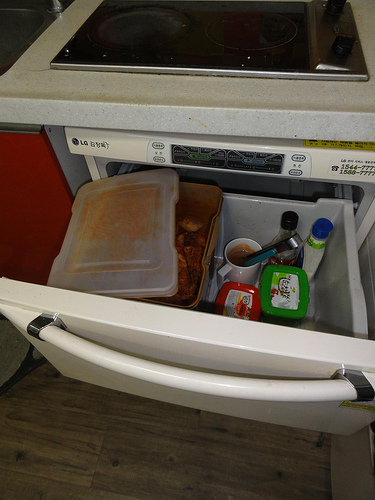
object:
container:
[258, 265, 309, 319]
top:
[215, 282, 260, 319]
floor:
[4, 355, 374, 500]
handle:
[25, 312, 375, 402]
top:
[2, 0, 373, 111]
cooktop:
[49, 0, 369, 80]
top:
[48, 167, 179, 296]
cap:
[312, 218, 332, 239]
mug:
[216, 238, 263, 283]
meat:
[182, 221, 203, 231]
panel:
[170, 142, 286, 176]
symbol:
[331, 163, 340, 175]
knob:
[330, 32, 357, 58]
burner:
[87, 3, 189, 51]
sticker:
[303, 137, 374, 153]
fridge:
[3, 128, 374, 437]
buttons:
[285, 151, 314, 183]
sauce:
[77, 175, 162, 254]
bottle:
[302, 217, 331, 281]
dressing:
[300, 235, 324, 281]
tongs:
[238, 233, 304, 265]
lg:
[70, 137, 91, 147]